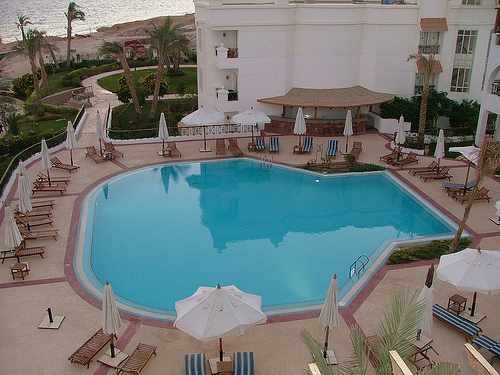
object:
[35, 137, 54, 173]
umbrella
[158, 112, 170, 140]
umbrella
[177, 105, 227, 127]
umbrella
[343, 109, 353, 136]
umbrella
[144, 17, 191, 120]
palm trees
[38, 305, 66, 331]
umbrella holder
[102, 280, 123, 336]
umbrella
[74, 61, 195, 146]
walking path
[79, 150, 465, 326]
pool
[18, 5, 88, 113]
trees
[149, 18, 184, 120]
trees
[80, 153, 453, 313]
swimming pool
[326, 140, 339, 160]
chairs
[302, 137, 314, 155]
chairs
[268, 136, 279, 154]
chairs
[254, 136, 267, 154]
chairs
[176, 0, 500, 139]
building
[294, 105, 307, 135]
umbrella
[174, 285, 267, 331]
umbrella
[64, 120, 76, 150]
umbrella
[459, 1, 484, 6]
windows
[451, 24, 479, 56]
windows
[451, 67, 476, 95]
windows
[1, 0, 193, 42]
water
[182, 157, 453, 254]
reflection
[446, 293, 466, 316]
table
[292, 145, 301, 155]
table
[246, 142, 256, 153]
table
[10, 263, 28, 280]
table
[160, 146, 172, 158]
table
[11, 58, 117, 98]
bushes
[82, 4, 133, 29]
ocean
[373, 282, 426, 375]
leaves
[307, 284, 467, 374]
tree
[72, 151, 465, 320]
water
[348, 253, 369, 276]
pool ladder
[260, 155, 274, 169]
pool ladder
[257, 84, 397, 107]
awning